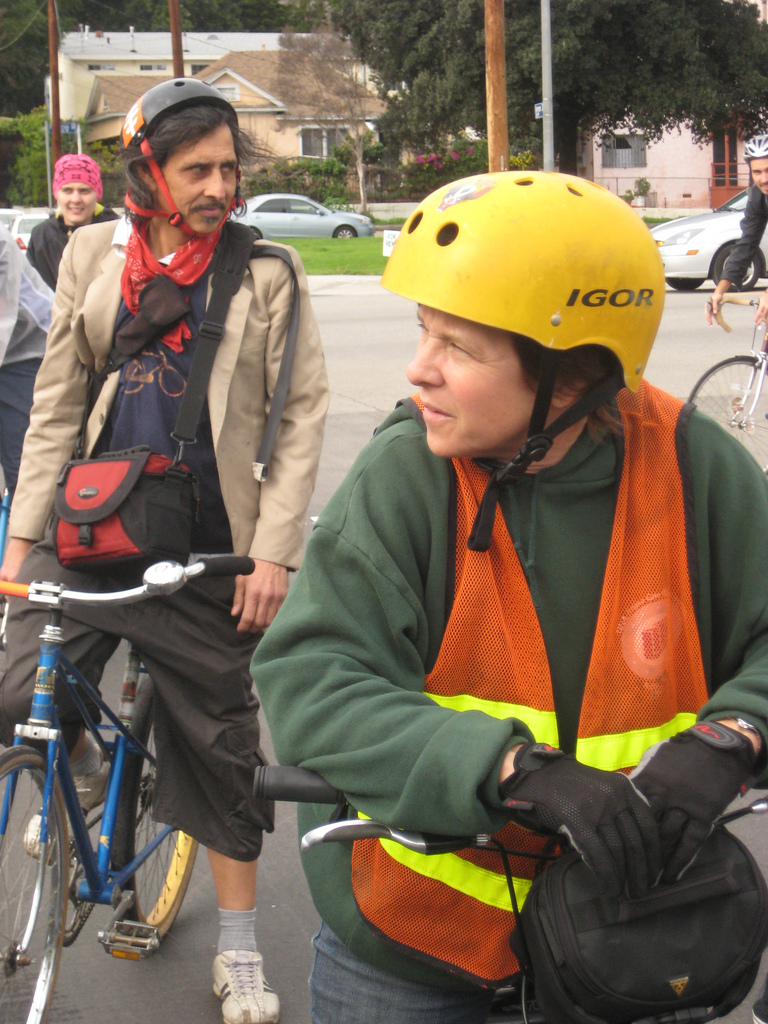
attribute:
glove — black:
[493, 739, 667, 902]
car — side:
[231, 190, 376, 243]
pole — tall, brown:
[482, 1, 508, 175]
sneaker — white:
[211, 951, 280, 1020]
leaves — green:
[327, 6, 765, 145]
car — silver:
[649, 187, 764, 286]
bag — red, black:
[56, 447, 197, 574]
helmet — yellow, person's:
[374, 166, 663, 388]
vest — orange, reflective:
[351, 372, 704, 991]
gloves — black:
[476, 716, 737, 905]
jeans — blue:
[292, 910, 491, 1017]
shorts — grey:
[10, 525, 276, 862]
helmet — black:
[117, 75, 248, 253]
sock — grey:
[212, 906, 270, 952]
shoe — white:
[208, 941, 282, 1021]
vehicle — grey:
[229, 192, 374, 238]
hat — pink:
[49, 152, 104, 199]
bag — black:
[505, 811, 763, 1021]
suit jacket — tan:
[1, 215, 331, 569]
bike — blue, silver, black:
[5, 551, 253, 1021]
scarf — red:
[117, 206, 235, 348]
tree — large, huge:
[320, 2, 766, 177]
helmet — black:
[120, 76, 241, 150]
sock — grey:
[218, 904, 258, 955]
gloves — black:
[497, 719, 753, 900]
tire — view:
[1, 733, 81, 1020]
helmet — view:
[370, 161, 679, 417]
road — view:
[261, 851, 305, 948]